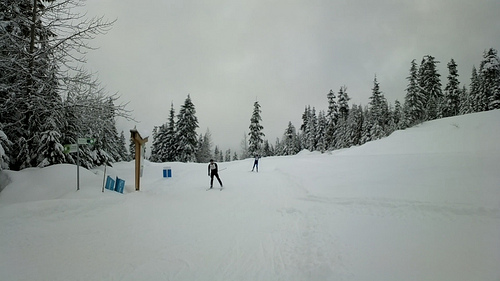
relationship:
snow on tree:
[270, 153, 400, 225] [169, 90, 204, 166]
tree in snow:
[169, 90, 204, 166] [270, 153, 400, 225]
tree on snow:
[169, 90, 204, 166] [270, 153, 400, 225]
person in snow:
[196, 153, 233, 195] [270, 153, 400, 225]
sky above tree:
[175, 13, 331, 73] [169, 90, 204, 166]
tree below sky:
[169, 90, 204, 166] [175, 13, 331, 73]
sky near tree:
[175, 13, 331, 73] [169, 90, 204, 166]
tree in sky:
[169, 90, 204, 166] [175, 13, 331, 73]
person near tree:
[196, 153, 233, 195] [169, 90, 204, 166]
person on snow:
[196, 153, 233, 195] [270, 153, 400, 225]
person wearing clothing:
[196, 153, 233, 195] [201, 159, 222, 192]